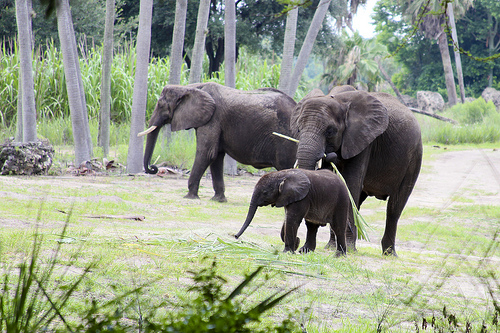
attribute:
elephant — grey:
[156, 74, 340, 201]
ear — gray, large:
[339, 93, 396, 162]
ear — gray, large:
[275, 167, 308, 211]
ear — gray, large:
[174, 85, 217, 140]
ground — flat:
[3, 142, 498, 330]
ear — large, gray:
[275, 169, 315, 206]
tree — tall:
[446, 46, 494, 101]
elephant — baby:
[232, 167, 349, 258]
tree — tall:
[53, 0, 96, 167]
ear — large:
[168, 85, 213, 132]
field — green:
[73, 49, 413, 293]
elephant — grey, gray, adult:
[137, 80, 297, 201]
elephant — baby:
[236, 165, 359, 258]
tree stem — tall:
[128, 0, 153, 178]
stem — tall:
[86, 63, 185, 185]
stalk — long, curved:
[270, 127, 372, 247]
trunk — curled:
[143, 122, 161, 174]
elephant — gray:
[222, 165, 364, 252]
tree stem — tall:
[278, 4, 298, 111]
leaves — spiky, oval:
[0, 122, 498, 331]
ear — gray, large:
[169, 85, 216, 133]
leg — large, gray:
[185, 115, 222, 198]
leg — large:
[380, 175, 417, 257]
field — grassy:
[15, 187, 452, 323]